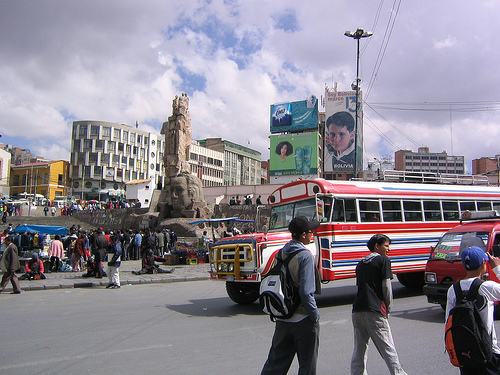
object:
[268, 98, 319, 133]
billboard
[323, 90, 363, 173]
billboard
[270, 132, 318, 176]
billboard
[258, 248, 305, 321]
backpack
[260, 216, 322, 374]
man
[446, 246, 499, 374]
boy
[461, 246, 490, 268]
baseball cap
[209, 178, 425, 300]
bus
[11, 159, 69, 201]
house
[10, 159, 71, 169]
roof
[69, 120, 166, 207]
building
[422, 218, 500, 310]
vehicle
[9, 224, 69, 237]
canopy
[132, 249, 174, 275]
person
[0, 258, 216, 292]
sidewalk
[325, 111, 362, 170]
person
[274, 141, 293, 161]
person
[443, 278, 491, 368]
backpack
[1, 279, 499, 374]
street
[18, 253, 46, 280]
person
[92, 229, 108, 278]
person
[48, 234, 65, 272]
person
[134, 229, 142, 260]
person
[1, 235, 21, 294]
man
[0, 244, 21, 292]
suit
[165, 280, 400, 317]
shadow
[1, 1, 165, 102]
clouds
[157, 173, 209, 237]
bust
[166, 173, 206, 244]
man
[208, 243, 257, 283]
grill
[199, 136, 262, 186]
building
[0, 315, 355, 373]
line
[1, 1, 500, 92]
sky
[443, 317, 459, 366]
orange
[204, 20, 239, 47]
blue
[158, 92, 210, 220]
statue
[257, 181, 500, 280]
side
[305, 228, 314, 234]
glasses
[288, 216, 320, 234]
cap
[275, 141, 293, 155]
hair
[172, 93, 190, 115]
figures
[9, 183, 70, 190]
stripes